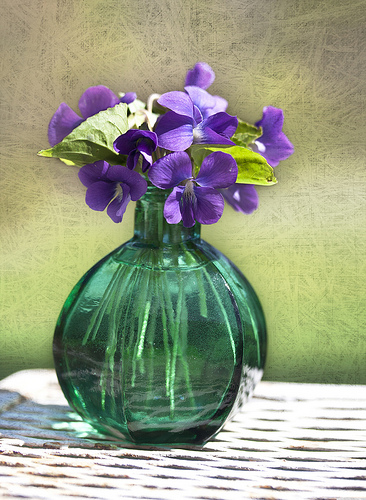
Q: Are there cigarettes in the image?
A: No, there are no cigarettes.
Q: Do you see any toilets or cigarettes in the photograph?
A: No, there are no cigarettes or toilets.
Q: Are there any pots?
A: No, there are no pots.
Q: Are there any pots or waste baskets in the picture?
A: No, there are no pots or waste baskets.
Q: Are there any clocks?
A: No, there are no clocks.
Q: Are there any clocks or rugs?
A: No, there are no clocks or rugs.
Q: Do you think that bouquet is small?
A: Yes, the bouquet is small.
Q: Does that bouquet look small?
A: Yes, the bouquet is small.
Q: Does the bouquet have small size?
A: Yes, the bouquet is small.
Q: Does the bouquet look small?
A: Yes, the bouquet is small.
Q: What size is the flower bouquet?
A: The flower bouquet is small.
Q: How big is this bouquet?
A: The bouquet is small.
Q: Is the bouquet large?
A: No, the bouquet is small.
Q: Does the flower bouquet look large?
A: No, the flower bouquet is small.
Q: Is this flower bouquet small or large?
A: The flower bouquet is small.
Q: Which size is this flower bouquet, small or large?
A: The flower bouquet is small.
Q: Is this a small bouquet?
A: Yes, this is a small bouquet.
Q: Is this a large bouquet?
A: No, this is a small bouquet.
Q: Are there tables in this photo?
A: Yes, there is a table.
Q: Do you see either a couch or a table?
A: Yes, there is a table.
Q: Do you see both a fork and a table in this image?
A: No, there is a table but no forks.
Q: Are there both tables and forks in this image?
A: No, there is a table but no forks.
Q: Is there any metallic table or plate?
A: Yes, there is a metal table.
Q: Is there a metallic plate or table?
A: Yes, there is a metal table.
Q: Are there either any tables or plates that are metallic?
A: Yes, the table is metallic.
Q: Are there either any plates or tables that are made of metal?
A: Yes, the table is made of metal.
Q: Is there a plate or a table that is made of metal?
A: Yes, the table is made of metal.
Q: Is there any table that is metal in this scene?
A: Yes, there is a metal table.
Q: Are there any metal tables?
A: Yes, there is a metal table.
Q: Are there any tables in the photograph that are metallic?
A: Yes, there is a table that is metallic.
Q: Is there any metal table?
A: Yes, there is a table that is made of metal.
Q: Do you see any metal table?
A: Yes, there is a table that is made of metal.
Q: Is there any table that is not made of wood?
A: Yes, there is a table that is made of metal.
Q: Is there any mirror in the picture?
A: No, there are no mirrors.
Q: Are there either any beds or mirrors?
A: No, there are no mirrors or beds.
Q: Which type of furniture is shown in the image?
A: The furniture is a table.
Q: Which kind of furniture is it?
A: The piece of furniture is a table.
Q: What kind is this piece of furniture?
A: This is a table.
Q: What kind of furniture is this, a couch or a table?
A: This is a table.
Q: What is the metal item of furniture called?
A: The piece of furniture is a table.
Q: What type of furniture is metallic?
A: The furniture is a table.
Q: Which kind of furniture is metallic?
A: The furniture is a table.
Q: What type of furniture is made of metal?
A: The furniture is a table.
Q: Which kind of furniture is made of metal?
A: The furniture is a table.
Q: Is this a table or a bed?
A: This is a table.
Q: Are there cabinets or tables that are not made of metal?
A: No, there is a table but it is made of metal.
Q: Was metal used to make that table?
A: Yes, the table is made of metal.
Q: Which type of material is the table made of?
A: The table is made of metal.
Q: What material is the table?
A: The table is made of metal.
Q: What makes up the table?
A: The table is made of metal.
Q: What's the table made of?
A: The table is made of metal.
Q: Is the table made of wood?
A: No, the table is made of metal.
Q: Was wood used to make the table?
A: No, the table is made of metal.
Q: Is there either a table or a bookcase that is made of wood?
A: No, there is a table but it is made of metal.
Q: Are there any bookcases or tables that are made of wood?
A: No, there is a table but it is made of metal.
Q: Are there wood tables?
A: No, there is a table but it is made of metal.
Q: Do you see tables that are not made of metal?
A: No, there is a table but it is made of metal.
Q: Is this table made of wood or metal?
A: The table is made of metal.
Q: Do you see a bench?
A: No, there are no benches.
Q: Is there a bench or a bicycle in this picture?
A: No, there are no benches or bicycles.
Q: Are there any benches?
A: No, there are no benches.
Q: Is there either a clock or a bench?
A: No, there are no benches or clocks.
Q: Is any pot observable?
A: No, there are no pots.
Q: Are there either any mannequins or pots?
A: No, there are no pots or mannequins.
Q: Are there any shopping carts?
A: No, there are no shopping carts.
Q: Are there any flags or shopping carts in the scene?
A: No, there are no shopping carts or flags.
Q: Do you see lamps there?
A: No, there are no lamps.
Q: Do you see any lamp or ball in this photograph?
A: No, there are no lamps or balls.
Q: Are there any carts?
A: No, there are no carts.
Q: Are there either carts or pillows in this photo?
A: No, there are no carts or pillows.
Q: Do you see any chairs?
A: No, there are no chairs.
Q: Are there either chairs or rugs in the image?
A: No, there are no chairs or rugs.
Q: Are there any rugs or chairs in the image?
A: No, there are no chairs or rugs.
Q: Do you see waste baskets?
A: No, there are no waste baskets.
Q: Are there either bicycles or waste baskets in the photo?
A: No, there are no waste baskets or bicycles.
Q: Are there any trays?
A: No, there are no trays.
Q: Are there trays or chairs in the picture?
A: No, there are no trays or chairs.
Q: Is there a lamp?
A: No, there are no lamps.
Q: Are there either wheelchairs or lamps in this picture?
A: No, there are no lamps or wheelchairs.